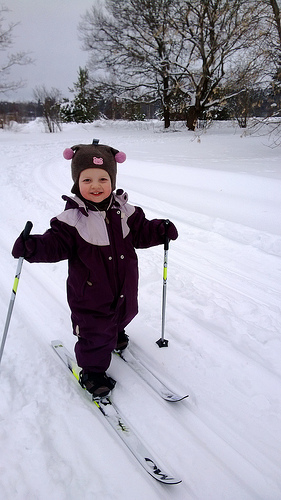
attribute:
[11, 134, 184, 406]
girl — young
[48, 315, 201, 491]
skis — white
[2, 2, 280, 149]
trees — bare, tall, brown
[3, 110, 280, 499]
snow — white, light, thick, large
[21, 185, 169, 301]
jacket — brown, pink, purple, dark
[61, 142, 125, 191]
cap — pink, brown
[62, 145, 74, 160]
ball — fuzzy, pink, little, round, small, light, bright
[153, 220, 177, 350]
pole — thin, long, skinny, white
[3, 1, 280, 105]
sky — grey, foggy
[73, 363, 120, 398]
boot — black, dark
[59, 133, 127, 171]
hat — brown, pink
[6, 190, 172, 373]
suit — purple